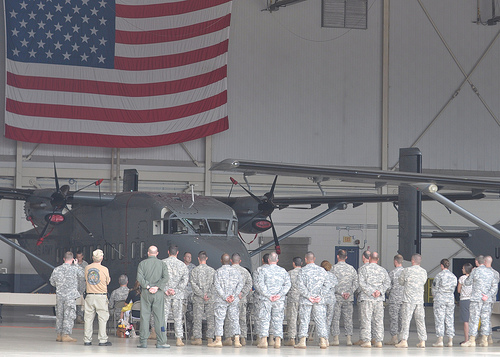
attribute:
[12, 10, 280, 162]
flag — large 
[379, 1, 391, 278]
pole — white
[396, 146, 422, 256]
pillar — tall, grey, metal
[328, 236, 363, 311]
door — yellow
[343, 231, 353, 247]
sign — small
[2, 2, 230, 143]
flag — giant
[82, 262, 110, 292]
shirt — peach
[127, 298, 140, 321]
chair — folding